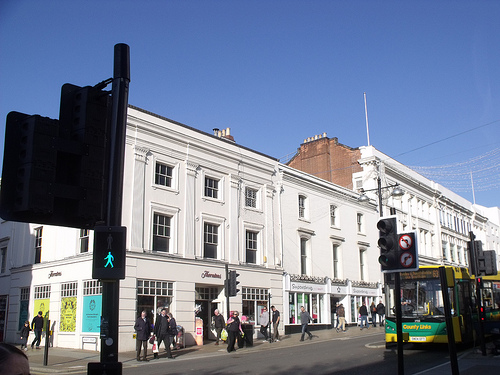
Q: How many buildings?
A: One.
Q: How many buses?
A: Two.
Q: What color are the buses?
A: Green and yellow.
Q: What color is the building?
A: Brown and white.